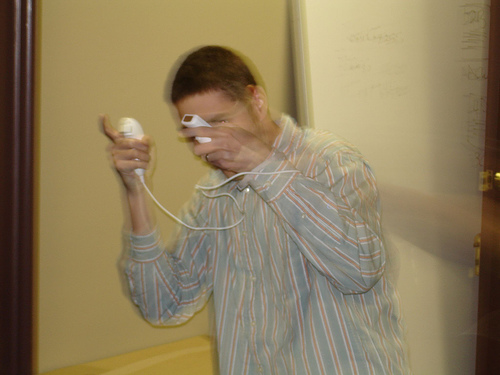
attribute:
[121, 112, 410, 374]
shirt — striped, long sleeved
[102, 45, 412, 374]
man — standing, playing, moving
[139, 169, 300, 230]
cord — white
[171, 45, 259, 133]
hair — dark, black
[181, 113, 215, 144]
wiimote — white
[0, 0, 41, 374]
wood — dark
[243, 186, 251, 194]
button — small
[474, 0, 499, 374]
door — dark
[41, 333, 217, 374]
couch — yellow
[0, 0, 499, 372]
image — blurry